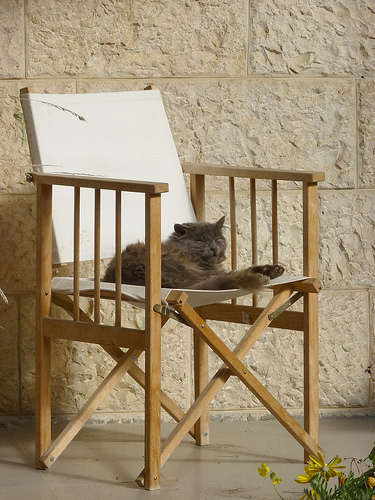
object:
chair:
[14, 81, 331, 498]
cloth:
[28, 87, 193, 232]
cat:
[102, 215, 281, 288]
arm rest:
[20, 167, 171, 193]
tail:
[190, 270, 272, 294]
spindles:
[63, 184, 133, 330]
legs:
[34, 313, 329, 484]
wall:
[5, 7, 374, 415]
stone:
[256, 6, 374, 85]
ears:
[166, 214, 229, 235]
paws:
[255, 264, 290, 284]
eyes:
[190, 232, 225, 244]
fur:
[123, 245, 144, 283]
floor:
[13, 418, 367, 499]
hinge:
[148, 307, 190, 331]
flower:
[304, 447, 342, 492]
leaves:
[310, 481, 363, 499]